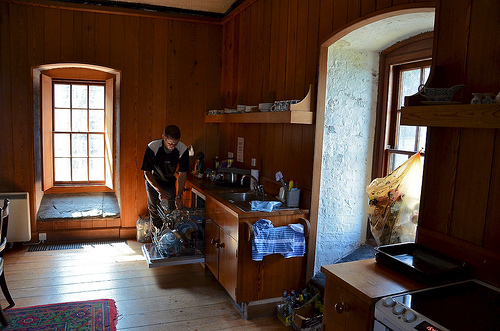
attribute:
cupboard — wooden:
[205, 115, 307, 127]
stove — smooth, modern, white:
[377, 303, 402, 330]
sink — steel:
[230, 193, 257, 205]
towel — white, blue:
[254, 232, 297, 252]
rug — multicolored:
[21, 296, 124, 330]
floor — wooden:
[21, 256, 141, 294]